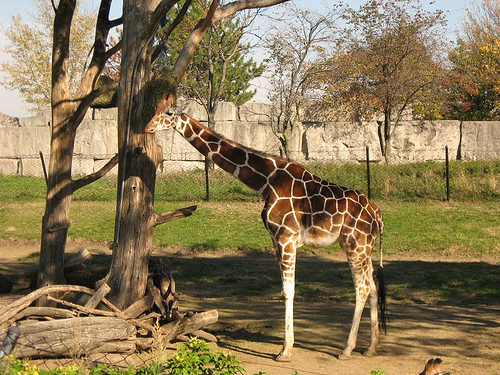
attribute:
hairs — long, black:
[374, 266, 387, 335]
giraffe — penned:
[106, 76, 420, 363]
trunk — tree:
[102, 2, 160, 300]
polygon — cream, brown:
[269, 170, 293, 196]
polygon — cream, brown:
[289, 178, 306, 197]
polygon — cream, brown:
[267, 197, 290, 224]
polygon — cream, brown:
[285, 161, 306, 181]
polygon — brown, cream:
[292, 197, 312, 214]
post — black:
[442, 145, 451, 201]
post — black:
[364, 145, 373, 200]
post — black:
[201, 155, 213, 202]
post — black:
[37, 150, 47, 182]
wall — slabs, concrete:
[0, 118, 499, 175]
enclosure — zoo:
[0, 197, 499, 374]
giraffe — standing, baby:
[139, 85, 386, 366]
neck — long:
[179, 118, 264, 190]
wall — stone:
[1, 97, 497, 166]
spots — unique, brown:
[248, 158, 380, 248]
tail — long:
[366, 208, 392, 338]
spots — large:
[259, 156, 378, 256]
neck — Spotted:
[181, 110, 267, 189]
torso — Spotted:
[261, 154, 381, 257]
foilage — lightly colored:
[309, 3, 441, 128]